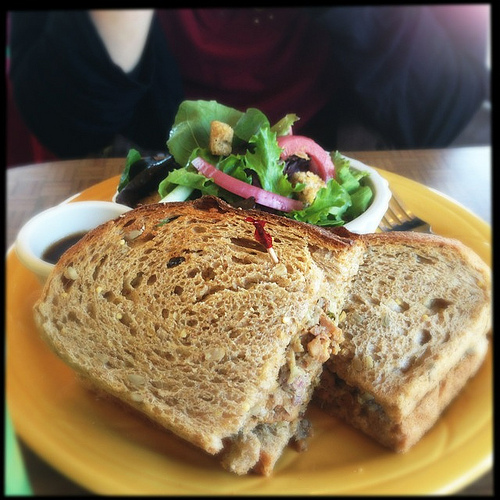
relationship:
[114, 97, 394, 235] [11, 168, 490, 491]
salad on top of plate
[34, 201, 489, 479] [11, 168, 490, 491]
sandwich on top of plate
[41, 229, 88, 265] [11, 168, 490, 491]
sauce on top of plate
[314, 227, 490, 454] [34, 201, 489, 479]
bread part of sandwich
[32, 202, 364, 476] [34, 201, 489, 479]
bread part of sandwich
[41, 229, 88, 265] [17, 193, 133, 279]
sauce inside dish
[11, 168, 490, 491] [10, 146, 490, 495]
plate on top of table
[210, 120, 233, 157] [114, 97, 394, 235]
crouton on top of salad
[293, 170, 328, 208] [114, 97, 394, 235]
crouton on top of salad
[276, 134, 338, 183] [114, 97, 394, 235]
tomato on top of salad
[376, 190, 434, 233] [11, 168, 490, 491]
fork on top of plate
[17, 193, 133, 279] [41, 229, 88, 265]
dish holding sauce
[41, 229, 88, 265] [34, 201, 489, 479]
sauce underneath sandwich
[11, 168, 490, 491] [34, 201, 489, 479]
plate underneath sandwich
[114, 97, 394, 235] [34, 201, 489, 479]
salad next to sandwich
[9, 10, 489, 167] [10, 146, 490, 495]
person next to table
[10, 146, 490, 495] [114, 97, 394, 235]
table underneath salad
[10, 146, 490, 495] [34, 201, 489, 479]
table underneath sandwich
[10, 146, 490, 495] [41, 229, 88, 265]
table underneath sauce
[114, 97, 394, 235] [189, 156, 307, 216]
salad has onion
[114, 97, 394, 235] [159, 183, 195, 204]
salad has onion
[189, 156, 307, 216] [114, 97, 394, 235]
onion on top of salad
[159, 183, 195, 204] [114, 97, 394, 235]
onion on top of salad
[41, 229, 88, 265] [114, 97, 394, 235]
sauce for salad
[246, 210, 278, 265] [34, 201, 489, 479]
toothpick inside sandwich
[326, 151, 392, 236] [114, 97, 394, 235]
bowl for salad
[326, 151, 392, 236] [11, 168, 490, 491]
bowl on top of plate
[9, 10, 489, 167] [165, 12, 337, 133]
person wearing shirt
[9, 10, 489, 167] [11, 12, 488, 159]
person wearing sweater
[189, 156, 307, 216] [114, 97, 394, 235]
onion part of salad